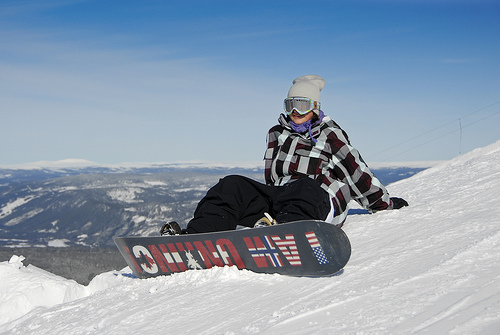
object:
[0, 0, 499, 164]
sky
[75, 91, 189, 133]
clouds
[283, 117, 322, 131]
neck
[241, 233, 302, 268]
word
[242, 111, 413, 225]
shirt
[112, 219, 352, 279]
snowboard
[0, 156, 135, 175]
mountains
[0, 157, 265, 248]
several mountains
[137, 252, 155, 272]
maple leaf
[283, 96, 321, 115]
goggle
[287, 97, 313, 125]
face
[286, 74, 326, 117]
knitted cap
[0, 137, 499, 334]
ground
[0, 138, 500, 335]
snowy slope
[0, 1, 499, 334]
landscape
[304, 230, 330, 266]
design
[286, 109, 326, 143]
scarf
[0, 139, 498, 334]
snow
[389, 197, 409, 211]
mitten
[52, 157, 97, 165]
peaks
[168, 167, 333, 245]
pants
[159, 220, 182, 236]
sneakers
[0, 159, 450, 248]
snow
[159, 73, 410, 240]
woman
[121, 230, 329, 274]
writing